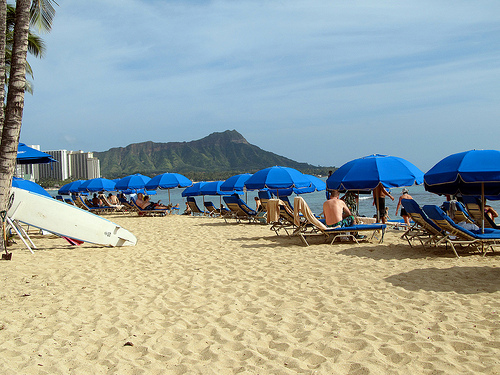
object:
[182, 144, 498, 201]
open umbrellas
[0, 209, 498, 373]
sand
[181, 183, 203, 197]
beach umbrella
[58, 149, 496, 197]
umbrellas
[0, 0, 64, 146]
palm trees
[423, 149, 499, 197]
blue umbrella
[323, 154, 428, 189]
blue umbrella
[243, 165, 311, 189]
blue umbrella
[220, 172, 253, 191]
blue umbrella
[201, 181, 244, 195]
blue umbrella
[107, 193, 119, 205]
people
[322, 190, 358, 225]
people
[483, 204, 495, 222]
people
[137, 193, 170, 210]
people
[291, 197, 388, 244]
chairs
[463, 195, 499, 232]
chairs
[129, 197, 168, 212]
chairs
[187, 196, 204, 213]
chairs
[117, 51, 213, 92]
clouds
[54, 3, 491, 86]
sky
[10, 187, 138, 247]
surfboard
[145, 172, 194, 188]
blue umbrella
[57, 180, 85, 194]
blue umbrella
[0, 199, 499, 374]
beach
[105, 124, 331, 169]
mountain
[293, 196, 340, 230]
towel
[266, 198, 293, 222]
towel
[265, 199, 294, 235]
chairs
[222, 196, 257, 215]
chair